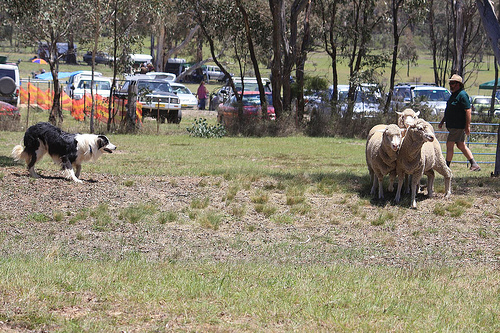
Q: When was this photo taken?
A: Daytime.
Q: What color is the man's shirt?
A: Green.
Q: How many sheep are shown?
A: 3.